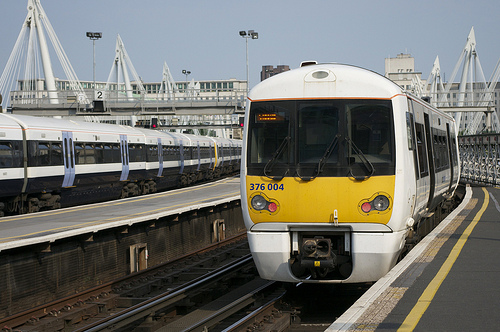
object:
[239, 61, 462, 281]
train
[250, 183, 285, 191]
number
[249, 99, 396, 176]
windshield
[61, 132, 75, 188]
door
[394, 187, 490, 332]
line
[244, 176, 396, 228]
strip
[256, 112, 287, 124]
sign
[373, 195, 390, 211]
light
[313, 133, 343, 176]
wiper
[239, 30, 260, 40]
light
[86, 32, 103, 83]
light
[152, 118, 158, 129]
light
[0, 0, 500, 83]
sky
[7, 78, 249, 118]
building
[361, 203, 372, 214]
headlight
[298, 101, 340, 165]
window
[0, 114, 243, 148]
roof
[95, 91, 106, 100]
square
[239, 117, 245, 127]
light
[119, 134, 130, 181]
doors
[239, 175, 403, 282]
front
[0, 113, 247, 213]
train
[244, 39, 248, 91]
pole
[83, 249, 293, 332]
track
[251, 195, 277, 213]
headlight